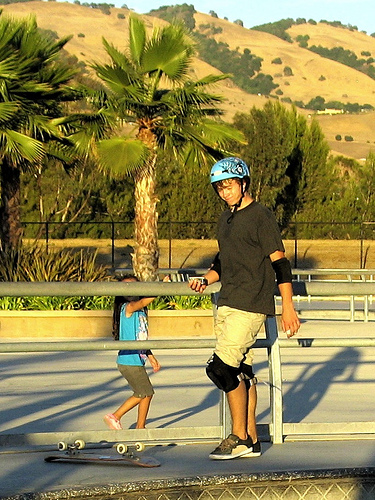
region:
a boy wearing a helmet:
[208, 147, 283, 223]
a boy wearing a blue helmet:
[205, 142, 261, 223]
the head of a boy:
[205, 180, 263, 221]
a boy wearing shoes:
[186, 399, 297, 468]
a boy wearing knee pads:
[192, 343, 291, 394]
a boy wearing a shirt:
[192, 188, 302, 373]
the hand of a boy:
[273, 285, 324, 345]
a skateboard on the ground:
[39, 413, 188, 489]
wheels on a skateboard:
[52, 433, 97, 455]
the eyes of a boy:
[212, 181, 240, 203]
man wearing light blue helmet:
[209, 156, 252, 184]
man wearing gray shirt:
[212, 196, 282, 317]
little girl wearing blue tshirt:
[112, 300, 152, 369]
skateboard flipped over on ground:
[40, 438, 169, 471]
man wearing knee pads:
[196, 345, 261, 395]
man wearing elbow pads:
[204, 250, 296, 290]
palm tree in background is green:
[76, 8, 244, 281]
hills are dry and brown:
[1, 1, 373, 169]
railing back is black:
[6, 215, 371, 280]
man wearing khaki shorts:
[207, 300, 268, 368]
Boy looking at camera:
[186, 157, 300, 458]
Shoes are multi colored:
[207, 433, 259, 458]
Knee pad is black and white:
[206, 352, 242, 391]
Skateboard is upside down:
[43, 440, 159, 467]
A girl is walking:
[103, 274, 169, 428]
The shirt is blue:
[116, 303, 149, 365]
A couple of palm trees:
[1, 12, 248, 282]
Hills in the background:
[1, 0, 374, 168]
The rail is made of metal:
[1, 282, 374, 446]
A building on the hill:
[316, 108, 343, 114]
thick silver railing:
[31, 273, 147, 311]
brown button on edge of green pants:
[136, 392, 149, 396]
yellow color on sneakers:
[229, 443, 255, 458]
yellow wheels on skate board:
[115, 442, 158, 455]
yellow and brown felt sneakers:
[208, 428, 270, 469]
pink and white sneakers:
[100, 411, 121, 423]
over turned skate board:
[37, 436, 184, 477]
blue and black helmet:
[194, 155, 277, 193]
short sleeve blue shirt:
[104, 298, 175, 368]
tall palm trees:
[100, 45, 208, 208]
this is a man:
[195, 150, 285, 454]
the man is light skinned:
[232, 392, 254, 430]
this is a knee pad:
[202, 358, 224, 384]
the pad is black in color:
[217, 365, 230, 377]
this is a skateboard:
[55, 438, 157, 489]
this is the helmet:
[212, 161, 246, 178]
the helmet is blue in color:
[213, 157, 228, 173]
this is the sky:
[246, 2, 271, 18]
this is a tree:
[263, 107, 299, 174]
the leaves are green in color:
[269, 108, 289, 148]